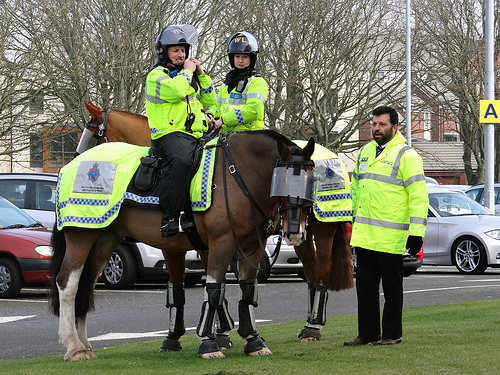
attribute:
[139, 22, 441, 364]
people — three, gathered together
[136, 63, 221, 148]
jacket — yellow, safety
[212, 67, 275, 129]
jacket — yellow, safety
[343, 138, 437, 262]
jacket — yellow, safety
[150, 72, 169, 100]
stripe — silver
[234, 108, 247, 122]
stripe — silver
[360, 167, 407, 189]
stripe — silver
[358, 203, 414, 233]
stripe — silver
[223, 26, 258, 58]
helmet — black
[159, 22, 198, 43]
visor — clear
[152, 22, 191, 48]
helmet — black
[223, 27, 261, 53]
helmet — black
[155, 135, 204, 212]
pants — black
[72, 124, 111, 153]
visor — clear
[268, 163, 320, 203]
visor — clear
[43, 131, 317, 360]
horse — large, brown, standing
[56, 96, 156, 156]
horse — large, brown, standing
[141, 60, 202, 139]
coat — bright yellow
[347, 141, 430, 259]
coat — bright yellow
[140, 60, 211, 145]
coat — bright yellow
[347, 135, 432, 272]
coat — bright yellow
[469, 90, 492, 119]
sign — yellow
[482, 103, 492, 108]
letter — A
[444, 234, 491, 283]
tire — car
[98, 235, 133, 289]
tire — car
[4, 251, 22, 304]
tire — car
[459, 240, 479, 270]
rim — metal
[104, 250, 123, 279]
rim — metal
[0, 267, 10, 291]
rim — metal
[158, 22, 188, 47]
helmet — his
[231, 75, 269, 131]
coat — yellow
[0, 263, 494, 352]
parking lot — paved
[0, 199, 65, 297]
car — red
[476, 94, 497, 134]
sign — yellow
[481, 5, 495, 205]
pole — silver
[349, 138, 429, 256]
raincoat — yellow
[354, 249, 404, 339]
pants — black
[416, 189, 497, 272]
car — silver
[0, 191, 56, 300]
car — red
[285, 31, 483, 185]
building — white